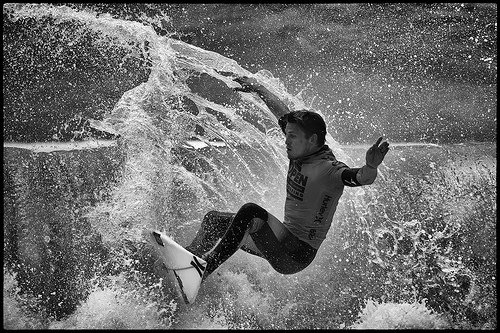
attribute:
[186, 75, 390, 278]
man — surfing, wet, falling, surfer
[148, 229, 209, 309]
board — white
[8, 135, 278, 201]
waves — rough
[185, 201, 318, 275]
pants — tight, dark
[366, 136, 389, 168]
hand — raised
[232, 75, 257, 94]
hand — raised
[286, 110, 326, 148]
hair — short, dark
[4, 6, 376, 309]
water — falling, splashing, rough, wavy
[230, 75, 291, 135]
arm — outstretched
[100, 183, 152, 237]
splash — white, frothy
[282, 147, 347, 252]
shirt — white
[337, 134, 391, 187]
arm — outstretched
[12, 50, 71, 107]
spray — white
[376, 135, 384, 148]
finger — spread